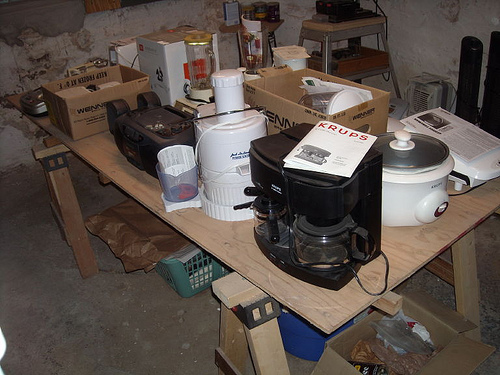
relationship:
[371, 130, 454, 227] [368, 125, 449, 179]
appliance with lid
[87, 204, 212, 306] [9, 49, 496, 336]
clutter under table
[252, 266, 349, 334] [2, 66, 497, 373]
scratches on table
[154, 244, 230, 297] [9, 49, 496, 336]
basket under table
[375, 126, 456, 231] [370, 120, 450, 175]
appliance with lid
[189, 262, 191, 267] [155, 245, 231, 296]
holes in basket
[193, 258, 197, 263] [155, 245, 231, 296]
holes in basket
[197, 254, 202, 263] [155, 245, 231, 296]
holes in basket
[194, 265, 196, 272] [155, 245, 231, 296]
holes in basket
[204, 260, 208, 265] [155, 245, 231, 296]
holes in basket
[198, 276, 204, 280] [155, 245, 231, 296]
holes in basket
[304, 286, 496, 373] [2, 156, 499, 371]
cardboard box on floor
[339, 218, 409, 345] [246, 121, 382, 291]
cord from coffee maker